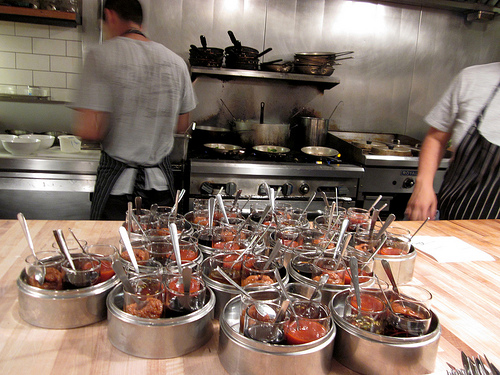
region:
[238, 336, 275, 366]
edge of a sufuria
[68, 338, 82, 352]
part of a shade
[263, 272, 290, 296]
handle of a spoon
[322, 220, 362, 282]
edge of a spoon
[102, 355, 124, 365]
edge of a shade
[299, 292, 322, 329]
part of a glass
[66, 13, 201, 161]
person in the kitchen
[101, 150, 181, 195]
apron tied on back of man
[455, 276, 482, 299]
table next to pot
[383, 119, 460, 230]
arm of the person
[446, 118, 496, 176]
apron on front of man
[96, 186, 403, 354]
many round pots on table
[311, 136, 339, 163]
pan on the stove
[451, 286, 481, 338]
light hitting the table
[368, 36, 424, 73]
silver wall in kitchen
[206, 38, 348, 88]
pans on the shelf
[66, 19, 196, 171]
guy working in the kitchen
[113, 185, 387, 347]
many items grouped together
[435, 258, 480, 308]
table next to pots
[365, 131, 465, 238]
arm of a person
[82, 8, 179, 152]
person with back towards camera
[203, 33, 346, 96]
pots on the shelf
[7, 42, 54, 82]
wall in front of person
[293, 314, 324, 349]
red stuff in pot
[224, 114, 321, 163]
stove next to man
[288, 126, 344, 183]
pan on the stove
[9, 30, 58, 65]
this is the wall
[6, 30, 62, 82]
the wall is made of bricks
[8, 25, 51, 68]
the wall is white in color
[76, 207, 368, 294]
these are several spoons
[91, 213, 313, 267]
the spoons are metallic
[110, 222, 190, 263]
the spoons are shiny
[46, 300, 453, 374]
these are several containers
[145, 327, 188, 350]
the containers are shiny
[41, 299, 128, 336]
the containers are metallic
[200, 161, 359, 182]
this is an oven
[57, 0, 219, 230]
man in kitchen with apron on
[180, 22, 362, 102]
several skillets on shelf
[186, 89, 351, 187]
pots and skillets cooking food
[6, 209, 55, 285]
silver colored spoon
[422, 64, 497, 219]
black with white stripes apron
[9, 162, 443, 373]
several food dishes on table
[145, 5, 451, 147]
stainless steel oven wall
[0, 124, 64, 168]
white dishes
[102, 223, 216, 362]
four different food dishes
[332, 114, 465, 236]
food cooking on flattop